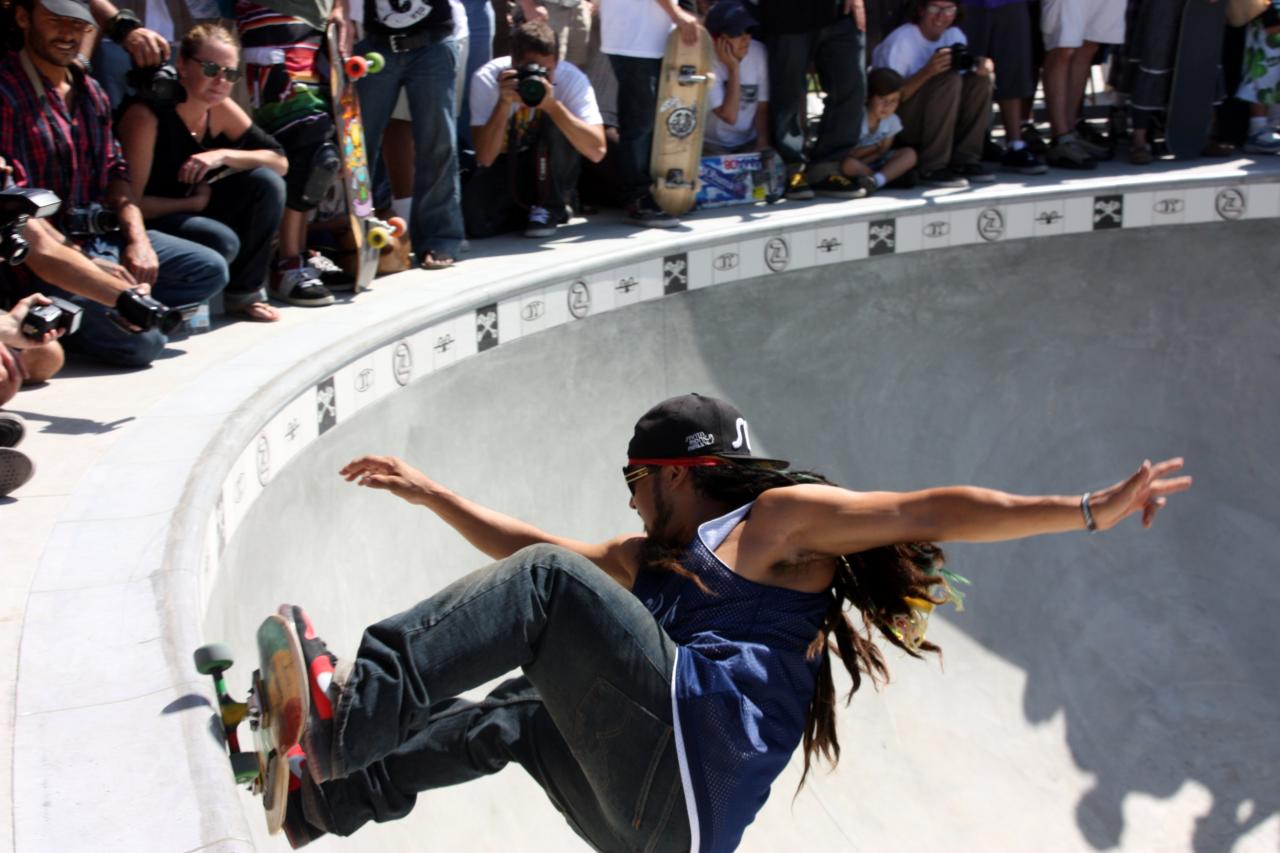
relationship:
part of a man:
[282, 600, 342, 849] [280, 392, 1194, 851]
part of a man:
[622, 392, 789, 542] [280, 392, 1194, 851]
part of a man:
[622, 384, 794, 544] [280, 392, 1194, 851]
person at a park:
[866, 2, 1017, 199] [7, 146, 1240, 848]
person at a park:
[843, 62, 929, 192] [7, 146, 1240, 848]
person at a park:
[757, 2, 875, 206] [7, 146, 1240, 848]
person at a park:
[701, 16, 789, 211] [7, 146, 1240, 848]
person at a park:
[587, 2, 708, 227] [7, 146, 1240, 848]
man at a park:
[467, 22, 605, 239] [7, 146, 1240, 848]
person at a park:
[338, 2, 472, 276] [7, 146, 1240, 848]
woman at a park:
[128, 18, 288, 320] [7, 146, 1240, 848]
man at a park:
[280, 392, 1194, 851] [7, 146, 1240, 848]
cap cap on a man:
[626, 392, 787, 469] [289, 417, 1233, 853]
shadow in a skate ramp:
[822, 234, 1278, 813] [614, 373, 1233, 853]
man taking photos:
[503, 133, 598, 195] [421, 266, 569, 370]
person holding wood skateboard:
[587, 2, 708, 227] [650, 16, 715, 216]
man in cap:
[190, 386, 1207, 842] [626, 392, 787, 469]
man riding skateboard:
[190, 386, 1207, 842] [199, 612, 317, 837]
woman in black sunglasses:
[110, 25, 296, 329] [187, 51, 242, 85]